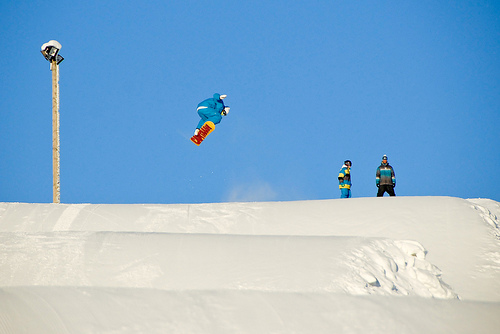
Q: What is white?
A: The ground.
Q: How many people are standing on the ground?
A: Two.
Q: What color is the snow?
A: White.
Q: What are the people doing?
A: Snowboarding.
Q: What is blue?
A: Sky.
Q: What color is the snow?
A: White.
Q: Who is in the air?
A: Snowboarder.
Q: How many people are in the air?
A: One.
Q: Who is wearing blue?
A: The snowboarder.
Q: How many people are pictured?
A: Three.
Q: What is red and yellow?
A: Snowboard.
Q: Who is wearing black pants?
A: Person on right.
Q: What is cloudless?
A: Sky.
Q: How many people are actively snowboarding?
A: 1.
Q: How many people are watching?
A: 2.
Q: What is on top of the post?
A: Lights.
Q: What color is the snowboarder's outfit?
A: Blue.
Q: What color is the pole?
A: Brown.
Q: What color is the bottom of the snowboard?
A: Red.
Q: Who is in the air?
A: Snowboard.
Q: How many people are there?
A: Three.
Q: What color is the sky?
A: Blue.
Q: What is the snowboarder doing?
A: Going over a jump.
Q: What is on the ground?
A: Snow.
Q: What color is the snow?
A: White.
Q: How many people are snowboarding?
A: One.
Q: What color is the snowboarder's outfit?
A: Blue.